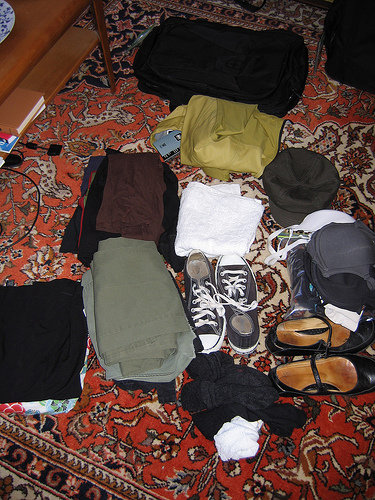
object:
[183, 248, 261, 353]
pair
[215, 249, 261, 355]
shoes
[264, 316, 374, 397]
pair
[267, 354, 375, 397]
dress shoes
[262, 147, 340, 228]
hat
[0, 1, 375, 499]
rug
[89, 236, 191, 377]
pants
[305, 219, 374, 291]
bra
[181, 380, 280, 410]
socks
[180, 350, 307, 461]
pile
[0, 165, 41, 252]
cord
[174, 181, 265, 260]
towel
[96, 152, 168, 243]
shirt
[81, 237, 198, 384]
pants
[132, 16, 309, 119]
bag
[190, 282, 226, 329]
shoelaces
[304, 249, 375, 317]
bras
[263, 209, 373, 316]
pile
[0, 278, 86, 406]
folded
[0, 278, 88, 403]
black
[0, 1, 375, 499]
red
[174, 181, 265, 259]
folded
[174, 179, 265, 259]
item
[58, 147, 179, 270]
stack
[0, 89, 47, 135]
book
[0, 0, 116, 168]
wood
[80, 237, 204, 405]
stack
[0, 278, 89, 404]
shorts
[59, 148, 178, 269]
shirts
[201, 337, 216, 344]
white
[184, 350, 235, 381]
black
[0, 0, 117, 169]
table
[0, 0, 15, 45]
dish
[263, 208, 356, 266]
bra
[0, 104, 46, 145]
books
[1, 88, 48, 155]
stack